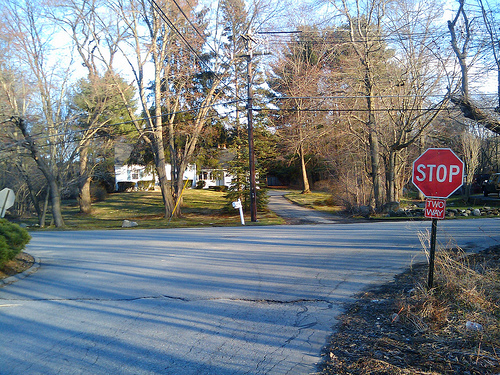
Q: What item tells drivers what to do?
A: A stop sign.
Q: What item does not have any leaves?
A: A tree.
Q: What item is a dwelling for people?
A: A house.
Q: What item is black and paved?
A: The road.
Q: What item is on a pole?
A: A sign.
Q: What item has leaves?
A: A tree.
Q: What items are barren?
A: A tree.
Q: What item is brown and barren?
A: A tree.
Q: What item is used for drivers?
A: A sign.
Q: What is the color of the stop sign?
A: Red.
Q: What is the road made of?
A: Concrete.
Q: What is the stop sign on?
A: Pole.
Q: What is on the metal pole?
A: Stop sign.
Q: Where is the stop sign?
A: Side of road.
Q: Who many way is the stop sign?
A: Two way.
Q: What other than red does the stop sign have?
A: White.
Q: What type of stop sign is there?
A: Two way.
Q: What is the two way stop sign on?
A: A pole.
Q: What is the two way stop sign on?
A: Metal pole.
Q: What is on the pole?
A: A stop sign.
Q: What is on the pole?
A: A stop sign.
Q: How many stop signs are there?
A: 2.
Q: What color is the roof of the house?
A: Black.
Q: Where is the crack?
A: Road.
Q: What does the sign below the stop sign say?
A: Two way.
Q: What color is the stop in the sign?
A: White.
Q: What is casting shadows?
A: Trees.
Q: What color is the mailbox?
A: White.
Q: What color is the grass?
A: Green.